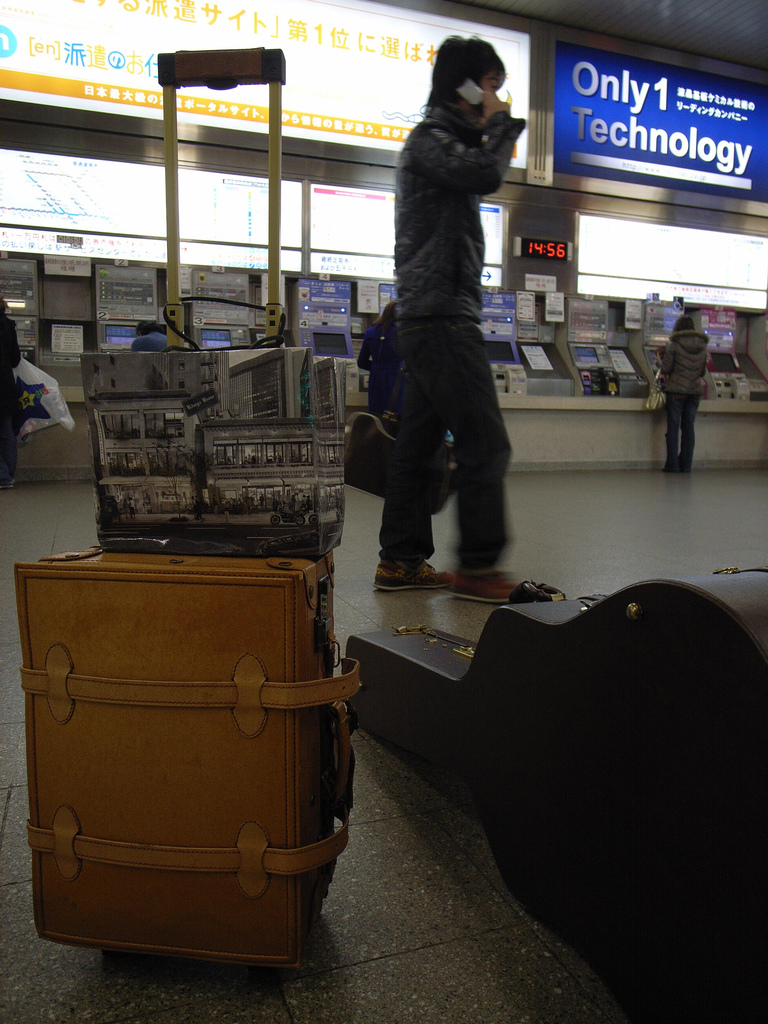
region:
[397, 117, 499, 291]
the coat is grey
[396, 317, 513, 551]
the jeans are dark blue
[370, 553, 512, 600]
the shoes are grey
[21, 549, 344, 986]
the suitcase is brown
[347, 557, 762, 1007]
a black guitar case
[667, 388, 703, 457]
the jeans are blue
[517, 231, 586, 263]
a sign with the time on it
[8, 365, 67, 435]
a big white bag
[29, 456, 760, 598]
the floor is grey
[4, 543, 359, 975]
brown suitcase on the floor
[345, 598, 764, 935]
black guitar case on the floor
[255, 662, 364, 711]
strap on the suitcase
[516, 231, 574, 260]
clock on the wall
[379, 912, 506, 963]
crack on the floor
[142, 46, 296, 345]
handle of the luggage carrier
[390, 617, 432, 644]
clasps on the guitar case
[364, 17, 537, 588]
man talking on a cellphone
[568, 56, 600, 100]
white letter on a sign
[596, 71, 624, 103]
white letter on a sign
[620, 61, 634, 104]
white letter on a sign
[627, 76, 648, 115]
white letter on a sign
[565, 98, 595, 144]
white letter on a sign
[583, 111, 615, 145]
white letter on a sign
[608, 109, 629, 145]
white letter on a sign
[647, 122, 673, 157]
white letter on a sign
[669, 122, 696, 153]
white letter on a sign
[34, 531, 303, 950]
suitcase on the ground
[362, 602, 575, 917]
suitcase on the ground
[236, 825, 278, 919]
handle on the suitcase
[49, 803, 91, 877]
handle on the suitcase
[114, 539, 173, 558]
handle on the suitcase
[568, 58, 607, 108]
a white letter on the sign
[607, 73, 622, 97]
a white letter on the sign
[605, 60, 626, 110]
a white letter on the sign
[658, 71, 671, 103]
a white letter on the sign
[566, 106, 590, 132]
a white letter on the sign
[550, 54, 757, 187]
White writing on a blue sign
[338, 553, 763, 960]
Black guitar case on the ground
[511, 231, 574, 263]
Time on a clock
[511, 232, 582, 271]
Clock on the wall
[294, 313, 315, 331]
Number on the kiosk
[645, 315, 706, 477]
Person standing at counter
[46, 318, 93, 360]
White sign near kiosk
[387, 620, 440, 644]
Metal buckle on guitar case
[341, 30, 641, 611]
man on a phone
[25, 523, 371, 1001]
a brown leather suitcase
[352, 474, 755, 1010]
a large guitar case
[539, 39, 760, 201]
a blue and white sign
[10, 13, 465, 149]
a white and yellow sign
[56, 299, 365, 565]
bag on top of suitcase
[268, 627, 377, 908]
straps on the suitcase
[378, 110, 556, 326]
a black leather coat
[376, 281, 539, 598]
a pair of jeans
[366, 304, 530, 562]
the mans legs below torso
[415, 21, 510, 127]
the mans head above shoulders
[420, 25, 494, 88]
the hair on the mans head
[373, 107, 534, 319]
the mans shirt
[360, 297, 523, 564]
the mans pants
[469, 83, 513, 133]
the mans hand at end of arm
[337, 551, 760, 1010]
guitar case near camera